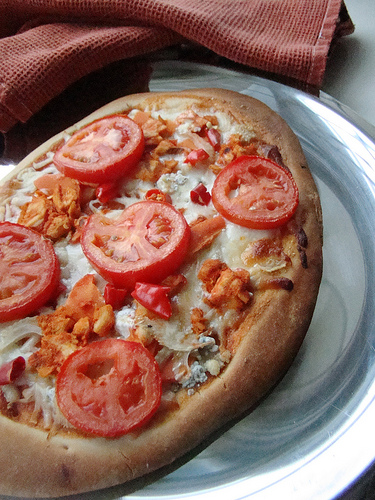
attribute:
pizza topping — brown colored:
[17, 174, 80, 240]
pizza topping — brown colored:
[199, 257, 249, 307]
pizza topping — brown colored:
[30, 305, 88, 375]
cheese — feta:
[156, 163, 194, 201]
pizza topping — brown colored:
[1, 87, 328, 497]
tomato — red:
[49, 111, 145, 184]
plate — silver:
[166, 73, 372, 283]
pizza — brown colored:
[57, 91, 329, 355]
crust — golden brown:
[2, 86, 322, 499]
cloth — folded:
[0, 1, 353, 79]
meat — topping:
[28, 284, 122, 383]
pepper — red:
[102, 277, 179, 323]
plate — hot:
[201, 63, 374, 498]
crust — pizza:
[224, 93, 284, 135]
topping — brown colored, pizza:
[193, 254, 258, 314]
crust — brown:
[203, 327, 306, 415]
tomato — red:
[213, 151, 301, 230]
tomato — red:
[0, 215, 63, 323]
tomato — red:
[56, 339, 162, 438]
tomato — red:
[82, 200, 195, 283]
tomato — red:
[50, 115, 144, 182]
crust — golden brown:
[248, 104, 327, 363]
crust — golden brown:
[110, 88, 277, 143]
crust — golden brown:
[1, 415, 189, 499]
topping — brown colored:
[196, 258, 249, 312]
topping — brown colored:
[56, 337, 160, 437]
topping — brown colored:
[27, 274, 116, 376]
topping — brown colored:
[1, 355, 25, 382]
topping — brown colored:
[0, 220, 60, 320]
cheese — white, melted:
[119, 304, 140, 336]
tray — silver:
[280, 378, 372, 466]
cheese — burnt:
[260, 275, 296, 296]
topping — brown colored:
[206, 151, 305, 230]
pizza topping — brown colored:
[154, 140, 172, 154]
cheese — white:
[124, 176, 201, 203]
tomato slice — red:
[81, 199, 190, 287]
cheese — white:
[2, 105, 285, 431]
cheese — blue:
[115, 304, 140, 342]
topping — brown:
[139, 106, 168, 144]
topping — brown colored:
[188, 305, 209, 337]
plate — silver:
[0, 59, 375, 498]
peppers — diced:
[194, 179, 215, 212]